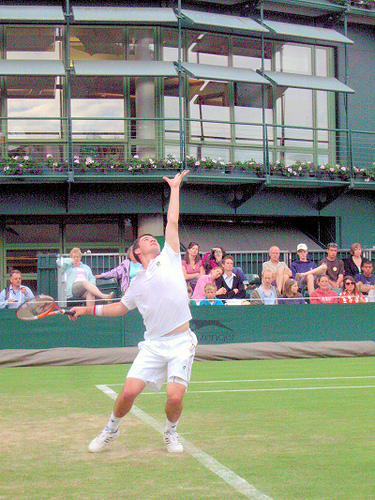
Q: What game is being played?
A: Tennis.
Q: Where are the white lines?
A: Court.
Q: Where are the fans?
A: Behind the wall.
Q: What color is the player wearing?
A: White.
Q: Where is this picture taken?
A: A tennis court.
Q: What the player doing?
A: Serving.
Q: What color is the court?
A: Green.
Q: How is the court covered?
A: With grass.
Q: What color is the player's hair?
A: Black.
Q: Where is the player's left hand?
A: The air.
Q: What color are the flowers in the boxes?
A: Purple.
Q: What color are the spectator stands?
A: Green.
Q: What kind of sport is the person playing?
A: Tennis.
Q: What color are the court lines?
A: White.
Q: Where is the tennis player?
A: Tennis court.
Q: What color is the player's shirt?
A: White.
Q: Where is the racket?
A: In the person's hand.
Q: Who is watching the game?
A: The crowd.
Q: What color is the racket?
A: Red.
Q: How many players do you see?
A: One.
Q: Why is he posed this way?
A: He is serving the ball.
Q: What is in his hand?
A: Tennis Racket.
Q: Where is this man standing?
A: On a tennis court.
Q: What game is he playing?
A: Tennis.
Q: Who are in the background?
A: Spectators.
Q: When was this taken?
A: During the daytime.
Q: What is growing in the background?
A: Flowers.